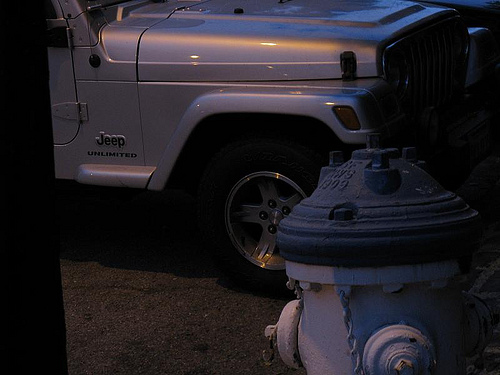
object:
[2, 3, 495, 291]
jeep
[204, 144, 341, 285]
wheel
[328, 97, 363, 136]
light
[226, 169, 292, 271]
center part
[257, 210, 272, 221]
big bolt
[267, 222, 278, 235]
nut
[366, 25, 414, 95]
front light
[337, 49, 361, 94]
black mark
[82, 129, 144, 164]
name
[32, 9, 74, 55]
mirror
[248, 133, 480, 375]
hydran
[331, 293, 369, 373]
chain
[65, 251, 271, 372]
concrete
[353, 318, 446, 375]
hose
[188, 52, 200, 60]
light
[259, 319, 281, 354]
bolt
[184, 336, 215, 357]
black object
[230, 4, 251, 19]
object